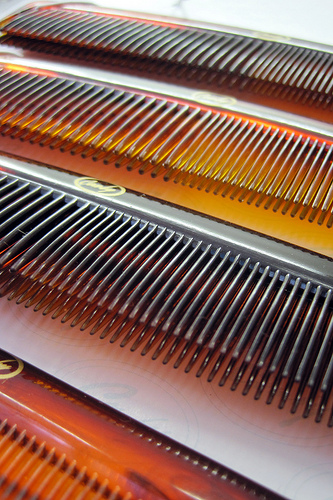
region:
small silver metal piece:
[310, 158, 332, 210]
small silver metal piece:
[271, 139, 310, 199]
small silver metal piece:
[256, 277, 314, 402]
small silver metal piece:
[155, 235, 243, 373]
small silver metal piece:
[97, 227, 177, 344]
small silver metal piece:
[49, 197, 133, 321]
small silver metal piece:
[0, 77, 58, 133]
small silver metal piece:
[67, 94, 136, 152]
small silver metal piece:
[195, 36, 233, 68]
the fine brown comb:
[76, 207, 235, 334]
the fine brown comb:
[75, 242, 221, 359]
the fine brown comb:
[81, 238, 250, 354]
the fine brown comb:
[83, 227, 244, 351]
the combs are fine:
[155, 97, 301, 229]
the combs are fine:
[156, 109, 279, 225]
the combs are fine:
[132, 100, 288, 219]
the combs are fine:
[145, 109, 282, 215]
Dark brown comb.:
[0, 1, 332, 97]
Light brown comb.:
[0, 344, 285, 499]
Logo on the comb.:
[71, 170, 127, 200]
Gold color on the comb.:
[70, 172, 127, 198]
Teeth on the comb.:
[0, 64, 331, 220]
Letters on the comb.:
[73, 174, 125, 199]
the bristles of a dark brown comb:
[79, 227, 154, 371]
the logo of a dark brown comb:
[69, 165, 127, 208]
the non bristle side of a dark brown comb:
[127, 183, 187, 252]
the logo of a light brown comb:
[3, 353, 29, 400]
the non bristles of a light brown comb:
[82, 392, 147, 459]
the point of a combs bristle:
[105, 302, 138, 363]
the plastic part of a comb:
[142, 105, 208, 151]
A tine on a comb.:
[105, 218, 170, 349]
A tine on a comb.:
[135, 217, 214, 369]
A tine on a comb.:
[200, 244, 260, 396]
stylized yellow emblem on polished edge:
[67, 167, 133, 201]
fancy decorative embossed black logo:
[49, 356, 207, 445]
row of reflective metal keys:
[10, 72, 331, 215]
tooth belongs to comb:
[231, 271, 290, 390]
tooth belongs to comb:
[158, 247, 231, 362]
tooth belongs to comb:
[96, 236, 193, 346]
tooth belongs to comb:
[28, 211, 123, 312]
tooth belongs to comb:
[0, 76, 55, 133]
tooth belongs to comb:
[38, 86, 102, 148]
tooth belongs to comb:
[200, 123, 254, 192]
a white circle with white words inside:
[75, 171, 126, 197]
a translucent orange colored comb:
[1, 349, 261, 498]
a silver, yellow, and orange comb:
[0, 51, 332, 224]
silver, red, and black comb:
[1, 2, 332, 99]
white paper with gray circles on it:
[1, 290, 332, 498]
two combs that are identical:
[0, 153, 332, 427]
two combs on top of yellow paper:
[0, 49, 332, 230]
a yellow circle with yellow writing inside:
[1, 354, 20, 383]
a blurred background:
[1, 0, 331, 44]